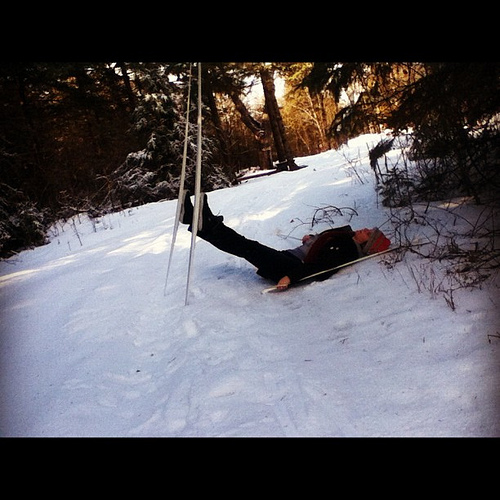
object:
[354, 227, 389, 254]
head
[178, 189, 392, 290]
woman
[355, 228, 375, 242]
face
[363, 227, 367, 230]
nose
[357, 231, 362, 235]
mouth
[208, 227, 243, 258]
legs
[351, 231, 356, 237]
chin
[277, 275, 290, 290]
hand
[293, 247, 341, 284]
arm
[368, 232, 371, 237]
eye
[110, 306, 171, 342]
snow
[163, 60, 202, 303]
skis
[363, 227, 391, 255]
hat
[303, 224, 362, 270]
jacket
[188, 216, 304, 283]
pants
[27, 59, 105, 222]
tree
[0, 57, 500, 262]
forest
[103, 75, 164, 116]
branches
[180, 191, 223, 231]
boots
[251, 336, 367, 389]
ground